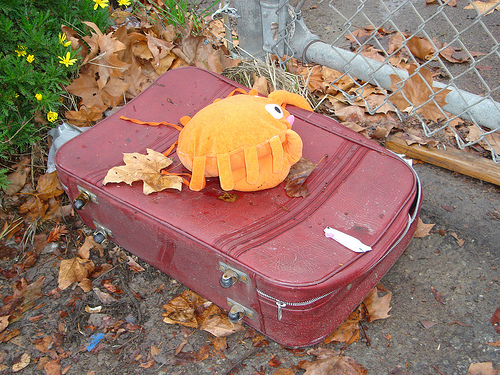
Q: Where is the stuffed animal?
A: On the suitcase.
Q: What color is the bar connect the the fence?
A: Silver.